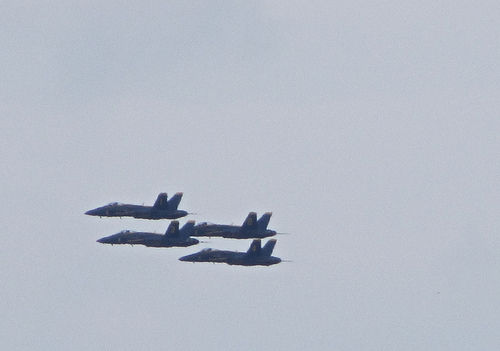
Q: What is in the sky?
A: Jets.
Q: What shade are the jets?
A: Black.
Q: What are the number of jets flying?
A: Four.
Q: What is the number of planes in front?
A: Two.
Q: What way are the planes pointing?
A: Left.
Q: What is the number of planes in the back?
A: Two.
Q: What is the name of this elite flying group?
A: The Blue Angels.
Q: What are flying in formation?
A: The jet planes.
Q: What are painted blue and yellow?
A: Planes.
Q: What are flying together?
A: The jets.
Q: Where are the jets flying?
A: In the sky.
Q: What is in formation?
A: A group of jets.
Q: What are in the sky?
A: Four planes.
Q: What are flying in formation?
A: Planes.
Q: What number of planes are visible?
A: Four planes.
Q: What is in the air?
A: Jets.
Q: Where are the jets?
A: In air.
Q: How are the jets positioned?
A: Close together.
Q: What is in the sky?
A: Planes.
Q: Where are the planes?
A: In the sky.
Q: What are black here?
A: The planes.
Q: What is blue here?
A: The sky.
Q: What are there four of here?
A: Planes.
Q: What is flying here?
A: Planes.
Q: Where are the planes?
A: In the air.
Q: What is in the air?
A: Airplanes.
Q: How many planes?
A: 4.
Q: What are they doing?
A: Formation.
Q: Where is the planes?
A: In the air.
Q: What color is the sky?
A: Gray.